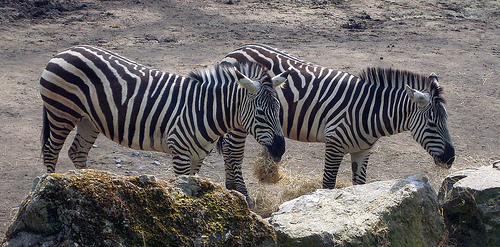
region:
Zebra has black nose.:
[263, 131, 300, 162]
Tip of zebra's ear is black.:
[225, 65, 247, 84]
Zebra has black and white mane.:
[185, 51, 284, 103]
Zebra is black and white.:
[72, 60, 217, 148]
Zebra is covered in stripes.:
[83, 60, 244, 169]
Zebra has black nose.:
[438, 145, 456, 166]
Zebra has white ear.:
[393, 77, 452, 129]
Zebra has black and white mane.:
[369, 57, 467, 129]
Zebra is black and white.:
[276, 41, 399, 170]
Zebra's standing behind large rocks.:
[130, 111, 468, 241]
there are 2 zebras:
[2, 34, 472, 212]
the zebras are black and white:
[200, 30, 467, 161]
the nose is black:
[256, 125, 296, 164]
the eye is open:
[242, 95, 274, 121]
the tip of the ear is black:
[215, 63, 259, 93]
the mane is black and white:
[349, 54, 454, 89]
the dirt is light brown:
[267, 4, 467, 74]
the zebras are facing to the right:
[173, 68, 469, 168]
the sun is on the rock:
[282, 172, 438, 234]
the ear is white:
[389, 75, 429, 113]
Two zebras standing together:
[18, 15, 480, 191]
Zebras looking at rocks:
[200, 39, 476, 193]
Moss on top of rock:
[47, 160, 238, 220]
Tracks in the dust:
[89, 10, 266, 76]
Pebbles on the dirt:
[349, 6, 479, 86]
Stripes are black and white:
[291, 75, 362, 117]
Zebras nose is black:
[262, 111, 294, 179]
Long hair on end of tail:
[29, 64, 59, 156]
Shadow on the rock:
[377, 166, 440, 241]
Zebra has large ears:
[392, 64, 444, 113]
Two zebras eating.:
[35, 41, 456, 183]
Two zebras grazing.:
[35, 40, 460, 183]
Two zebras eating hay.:
[35, 38, 457, 183]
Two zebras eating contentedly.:
[36, 40, 457, 180]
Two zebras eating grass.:
[35, 41, 455, 177]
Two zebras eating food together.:
[36, 40, 456, 180]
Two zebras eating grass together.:
[35, 40, 455, 175]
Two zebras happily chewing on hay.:
[37, 40, 457, 180]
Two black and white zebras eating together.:
[37, 41, 457, 188]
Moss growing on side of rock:
[70, 183, 222, 235]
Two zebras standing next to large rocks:
[35, 36, 460, 185]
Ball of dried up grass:
[256, 154, 281, 189]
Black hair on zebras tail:
[42, 101, 52, 151]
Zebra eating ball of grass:
[236, 67, 291, 184]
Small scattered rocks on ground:
[112, 153, 162, 170]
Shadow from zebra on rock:
[385, 172, 433, 195]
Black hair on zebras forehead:
[435, 85, 446, 112]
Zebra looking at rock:
[287, 56, 466, 184]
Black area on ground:
[7, 3, 99, 28]